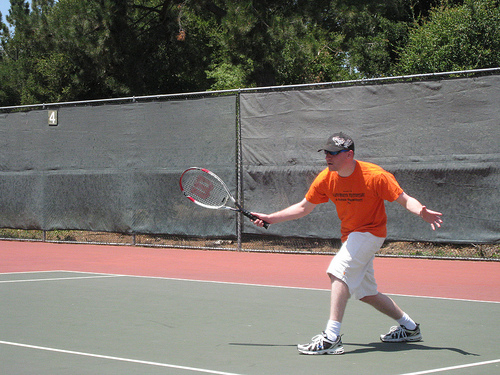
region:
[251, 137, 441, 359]
this is a man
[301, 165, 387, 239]
the man is wearing an orange t sshirt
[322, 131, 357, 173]
the man is wearing a black cap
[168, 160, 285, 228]
the man is holding a racket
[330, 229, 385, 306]
the man is wearing white shorts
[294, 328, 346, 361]
that is a shoe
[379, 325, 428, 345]
that is a shoe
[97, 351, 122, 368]
marking on the ground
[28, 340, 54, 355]
marking on the ground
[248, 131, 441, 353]
man in orange playing tennis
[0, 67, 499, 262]
metal fence around the tennis court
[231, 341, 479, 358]
shadow of a man playing tennis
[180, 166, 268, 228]
red and white tennis racket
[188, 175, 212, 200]
red logo of the brand of the racket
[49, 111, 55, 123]
number four on the fence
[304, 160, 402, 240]
orange shirt worn by a man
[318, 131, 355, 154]
black hat on a man's head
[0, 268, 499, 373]
green tennis court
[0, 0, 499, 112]
trees behind the fence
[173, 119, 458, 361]
person holding tennis racket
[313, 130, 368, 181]
person wearing a hat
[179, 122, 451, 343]
person wearing orange shirt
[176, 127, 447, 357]
person wearing a pair of sneakers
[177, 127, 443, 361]
person wearing a white shorts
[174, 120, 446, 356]
person is carrying a tennis racket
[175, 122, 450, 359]
man is playing tennis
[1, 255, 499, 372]
a tennis court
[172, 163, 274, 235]
a tennis racket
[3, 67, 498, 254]
a fence in the tennis court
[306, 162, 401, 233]
a bright orange t-shirt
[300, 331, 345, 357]
black sneaker with white stripes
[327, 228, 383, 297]
white knee length shorts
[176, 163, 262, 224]
red, white and black tennis racquet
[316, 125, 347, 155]
black cap with a sunvisor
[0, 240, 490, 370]
green tennis court with a red boarder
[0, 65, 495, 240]
grey tarps connected to tall chain link fencing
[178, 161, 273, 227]
tennis racquet made by Wilson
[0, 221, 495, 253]
a dirt ground shows beneath the fence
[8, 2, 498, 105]
trees tower behind the fence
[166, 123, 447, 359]
a man holding a tennis racket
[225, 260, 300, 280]
red concrete surface of the tennis court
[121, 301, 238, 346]
green concrete surface of the tennis court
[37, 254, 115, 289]
white lines painted on the tennis court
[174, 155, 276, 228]
a red and white tennis racket with a black handle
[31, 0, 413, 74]
trees growing outside the tennis court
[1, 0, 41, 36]
clear blue skies behind the trees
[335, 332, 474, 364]
shadow of the man cast on the ground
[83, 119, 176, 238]
black screen over the fence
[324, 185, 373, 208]
black lettering on an orange shirt